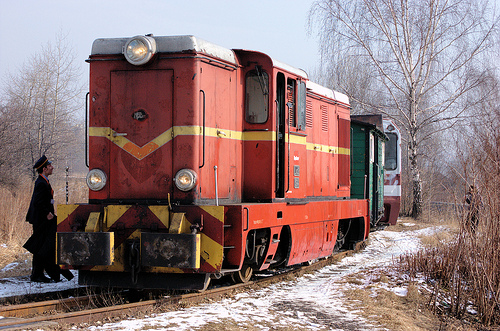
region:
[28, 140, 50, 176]
red and black hat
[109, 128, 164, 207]
heart on front of tain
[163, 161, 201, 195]
light on front of train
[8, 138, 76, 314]
conductor looking at train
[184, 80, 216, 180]
silver rail on side of train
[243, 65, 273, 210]
window on a train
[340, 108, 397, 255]
small green and black house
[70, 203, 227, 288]
yellow and red train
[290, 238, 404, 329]
snow on the ground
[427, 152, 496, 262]
person in the woods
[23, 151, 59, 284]
Person standing in front of a train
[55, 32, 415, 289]
Train on the railway tracks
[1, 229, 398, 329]
Railway tracks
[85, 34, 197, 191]
Lights on the head of the train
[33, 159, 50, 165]
Yellow line on the person's hat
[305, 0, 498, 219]
Tree grows next to train tracks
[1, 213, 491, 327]
Snow on the ground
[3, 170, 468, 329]
Dry grass on the ground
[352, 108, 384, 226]
Green car of the train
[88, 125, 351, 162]
Yellow line on the train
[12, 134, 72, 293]
conductor of a train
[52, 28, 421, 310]
train on metal tracks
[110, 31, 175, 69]
light on front of train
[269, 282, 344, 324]
white snow on ground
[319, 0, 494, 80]
bare tree in the background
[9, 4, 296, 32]
greyish blue sky in the distance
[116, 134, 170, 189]
painting of a red heart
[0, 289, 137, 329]
metal train tracks on the ground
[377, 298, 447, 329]
brown grass on the ground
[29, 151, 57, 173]
hat of a conductor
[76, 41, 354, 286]
an orange train car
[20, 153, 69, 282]
man standing next to a train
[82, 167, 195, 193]
headlights on the front of a train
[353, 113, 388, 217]
a green train car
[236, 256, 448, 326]
patch of snow in the dirt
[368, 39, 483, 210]
brown leafless tree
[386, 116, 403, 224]
white and rust colored train car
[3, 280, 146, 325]
a set of railroad tracks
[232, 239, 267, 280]
the wheel of a train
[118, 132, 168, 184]
heart design on the orange train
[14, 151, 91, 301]
conductor beside a train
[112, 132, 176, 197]
heart on front of train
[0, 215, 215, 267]
stoppers on front of train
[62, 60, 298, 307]
red and yellow train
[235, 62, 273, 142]
window on a train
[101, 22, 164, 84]
light on top of train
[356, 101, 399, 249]
small green house with black roof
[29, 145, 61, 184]
black and red hat